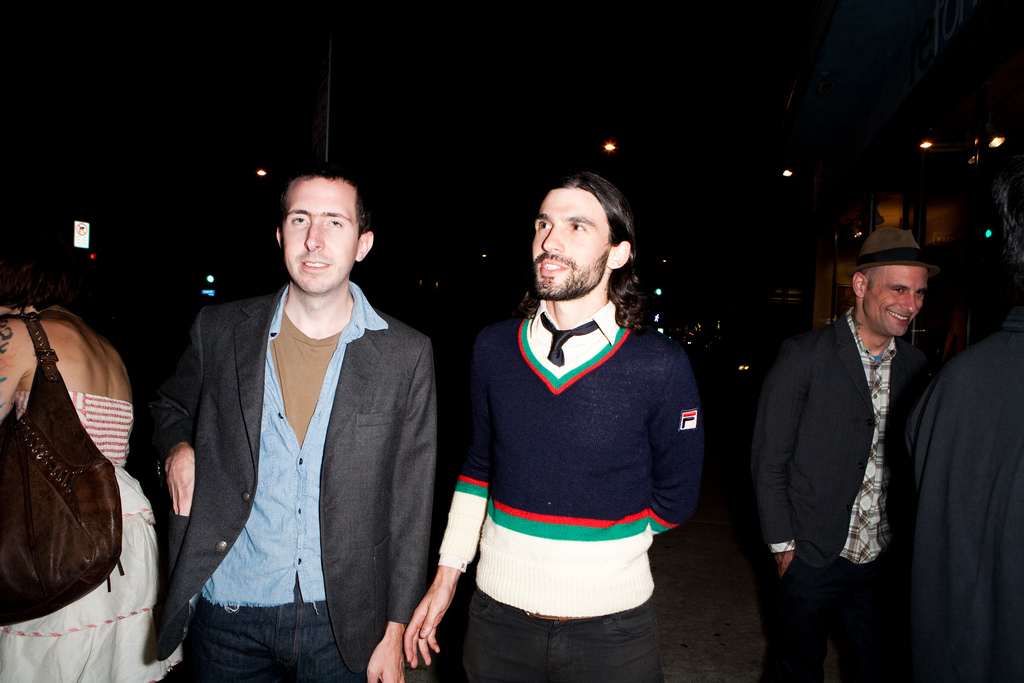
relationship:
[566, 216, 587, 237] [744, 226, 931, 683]
eye of a man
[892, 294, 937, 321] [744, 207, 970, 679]
nose of a man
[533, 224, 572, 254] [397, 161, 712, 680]
nose of a man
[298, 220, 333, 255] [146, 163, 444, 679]
nose of a man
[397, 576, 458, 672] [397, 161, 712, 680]
hand of a man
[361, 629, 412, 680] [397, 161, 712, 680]
hand of a man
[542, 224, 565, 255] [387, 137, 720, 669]
nose of man